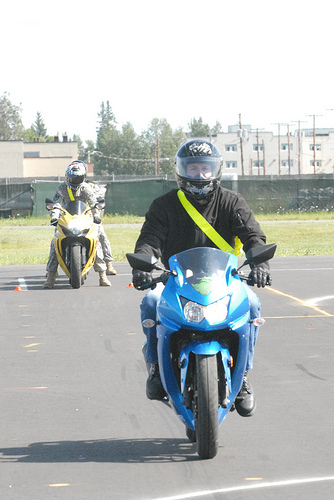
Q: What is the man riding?
A: A blue motorbike.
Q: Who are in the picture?
A: Two motorcycles with riders.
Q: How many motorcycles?
A: 2.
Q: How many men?
A: 2.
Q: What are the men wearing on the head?
A: Helmets.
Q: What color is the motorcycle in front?
A: Blue.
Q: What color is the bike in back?
A: Yellow.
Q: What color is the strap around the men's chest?
A: Yellow.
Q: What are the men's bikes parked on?
A: Concrete.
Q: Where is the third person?
A: Back of bike.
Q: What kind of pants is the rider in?
A: Jeans.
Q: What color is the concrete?
A: Black.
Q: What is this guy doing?
A: Riding motorcycle.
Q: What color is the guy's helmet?
A: Black.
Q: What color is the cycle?
A: Blue.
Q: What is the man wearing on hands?
A: Gloves.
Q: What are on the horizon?
A: Trees.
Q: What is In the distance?
A: Buildings.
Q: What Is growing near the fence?
A: Grass.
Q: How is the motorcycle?
A: In motion.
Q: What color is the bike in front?
A: Blue.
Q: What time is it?
A: Daytime.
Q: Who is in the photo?
A: Two men.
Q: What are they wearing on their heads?
A: Helmets.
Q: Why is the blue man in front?
A: Race.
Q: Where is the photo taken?
A: In a parking lot.